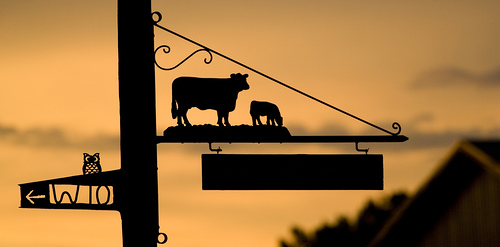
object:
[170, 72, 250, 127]
cow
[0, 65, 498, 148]
clouds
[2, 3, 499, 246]
sky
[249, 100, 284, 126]
cow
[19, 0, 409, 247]
sign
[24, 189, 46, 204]
arrow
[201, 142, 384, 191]
plate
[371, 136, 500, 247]
roof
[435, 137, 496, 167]
peak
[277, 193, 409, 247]
trees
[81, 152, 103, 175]
owl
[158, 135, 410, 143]
rail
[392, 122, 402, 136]
end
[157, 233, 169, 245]
hook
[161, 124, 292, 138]
ground shape